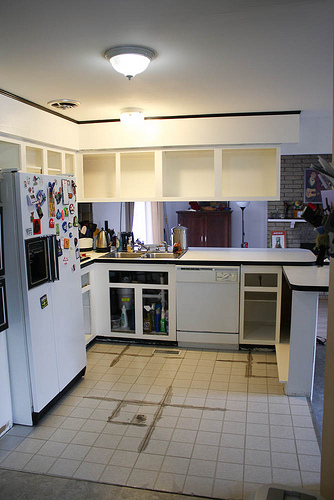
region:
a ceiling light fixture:
[101, 45, 156, 80]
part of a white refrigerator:
[4, 166, 88, 426]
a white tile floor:
[0, 346, 320, 498]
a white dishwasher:
[173, 263, 243, 347]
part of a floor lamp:
[234, 199, 251, 244]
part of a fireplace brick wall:
[268, 154, 307, 248]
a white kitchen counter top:
[179, 242, 314, 262]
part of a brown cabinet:
[174, 207, 231, 246]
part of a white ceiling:
[203, 60, 327, 101]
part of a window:
[133, 205, 152, 240]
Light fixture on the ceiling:
[96, 39, 161, 85]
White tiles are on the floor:
[0, 334, 320, 495]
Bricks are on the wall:
[261, 146, 328, 244]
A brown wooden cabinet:
[169, 202, 233, 247]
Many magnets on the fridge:
[10, 167, 84, 312]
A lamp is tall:
[228, 194, 250, 247]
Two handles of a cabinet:
[192, 228, 210, 246]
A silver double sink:
[92, 230, 188, 260]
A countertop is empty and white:
[179, 238, 319, 267]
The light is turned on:
[96, 38, 162, 81]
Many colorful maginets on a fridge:
[18, 173, 87, 283]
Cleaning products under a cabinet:
[106, 283, 166, 337]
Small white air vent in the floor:
[149, 344, 190, 362]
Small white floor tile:
[9, 435, 50, 459]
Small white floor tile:
[210, 457, 254, 484]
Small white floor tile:
[156, 448, 193, 477]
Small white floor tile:
[107, 438, 138, 469]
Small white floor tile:
[197, 382, 226, 404]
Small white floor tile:
[237, 396, 275, 423]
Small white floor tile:
[113, 365, 147, 387]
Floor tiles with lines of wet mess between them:
[87, 381, 206, 444]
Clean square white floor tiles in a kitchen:
[202, 422, 307, 479]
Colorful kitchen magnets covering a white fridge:
[42, 177, 79, 259]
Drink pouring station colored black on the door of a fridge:
[25, 233, 60, 293]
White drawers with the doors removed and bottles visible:
[100, 260, 175, 343]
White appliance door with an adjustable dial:
[172, 258, 239, 355]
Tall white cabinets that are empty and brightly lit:
[77, 147, 280, 198]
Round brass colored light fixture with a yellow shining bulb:
[104, 44, 150, 91]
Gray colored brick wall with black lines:
[282, 155, 304, 201]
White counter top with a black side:
[285, 264, 331, 293]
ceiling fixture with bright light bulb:
[101, 43, 158, 81]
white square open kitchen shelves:
[5, 133, 282, 204]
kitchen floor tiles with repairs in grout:
[86, 345, 311, 498]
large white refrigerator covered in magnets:
[0, 164, 86, 430]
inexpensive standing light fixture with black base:
[233, 199, 253, 247]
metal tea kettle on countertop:
[95, 225, 113, 253]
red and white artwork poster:
[266, 227, 289, 249]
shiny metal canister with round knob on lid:
[168, 222, 191, 251]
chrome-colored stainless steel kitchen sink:
[108, 238, 179, 261]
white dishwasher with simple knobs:
[173, 261, 243, 352]